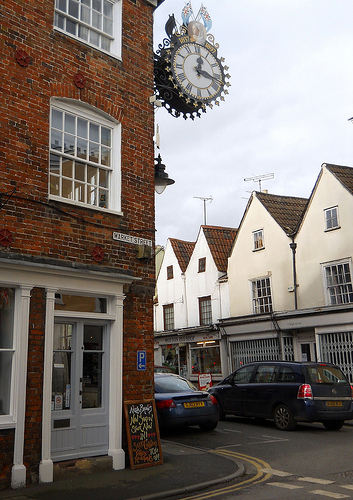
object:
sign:
[135, 349, 147, 372]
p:
[139, 353, 145, 363]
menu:
[124, 398, 164, 469]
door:
[50, 310, 113, 462]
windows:
[50, 320, 104, 410]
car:
[154, 372, 218, 432]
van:
[206, 361, 353, 432]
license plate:
[183, 401, 205, 408]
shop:
[0, 0, 163, 483]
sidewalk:
[2, 438, 353, 499]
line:
[159, 449, 267, 500]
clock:
[153, 21, 231, 121]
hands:
[194, 55, 223, 83]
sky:
[152, 0, 353, 248]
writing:
[128, 402, 154, 442]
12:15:
[193, 45, 224, 84]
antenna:
[242, 171, 275, 192]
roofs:
[227, 190, 310, 260]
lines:
[265, 469, 353, 500]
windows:
[46, 97, 124, 219]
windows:
[52, 0, 124, 65]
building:
[153, 162, 353, 389]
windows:
[250, 273, 273, 314]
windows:
[197, 296, 212, 327]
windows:
[322, 257, 353, 306]